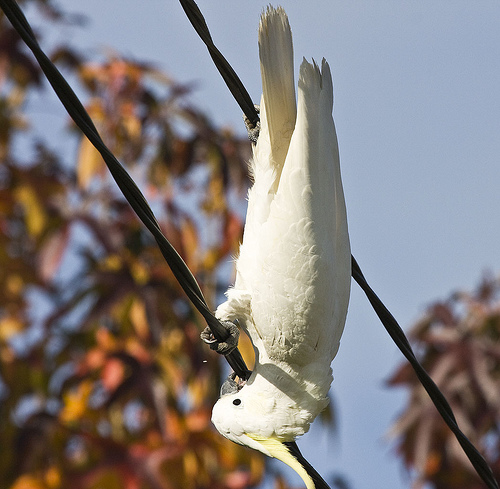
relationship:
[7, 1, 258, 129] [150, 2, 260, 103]
wire in sky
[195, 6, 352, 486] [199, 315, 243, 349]
bird has claw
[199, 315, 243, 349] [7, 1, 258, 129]
claw grips wire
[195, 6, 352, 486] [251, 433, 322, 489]
bird has feather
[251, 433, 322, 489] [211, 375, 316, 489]
feather on head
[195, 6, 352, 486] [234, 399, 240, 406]
bird has eye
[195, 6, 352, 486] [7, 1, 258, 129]
bird on wire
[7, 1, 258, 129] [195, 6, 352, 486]
wire behind bird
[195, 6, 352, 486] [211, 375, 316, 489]
bird has head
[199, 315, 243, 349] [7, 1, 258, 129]
claw on wire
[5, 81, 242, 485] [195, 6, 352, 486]
tree behind bird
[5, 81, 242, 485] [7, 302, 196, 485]
tree has leaves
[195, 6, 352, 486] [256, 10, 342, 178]
bird has tail feathers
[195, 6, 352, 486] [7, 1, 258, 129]
bird bites wire